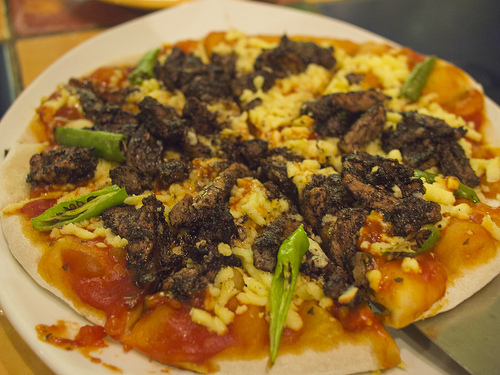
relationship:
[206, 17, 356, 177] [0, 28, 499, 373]
slice part of pizza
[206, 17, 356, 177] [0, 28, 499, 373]
slice cut from pizza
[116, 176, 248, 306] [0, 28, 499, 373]
topping on pizza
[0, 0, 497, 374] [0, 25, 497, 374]
white plate on table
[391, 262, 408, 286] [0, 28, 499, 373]
herb piece on pizza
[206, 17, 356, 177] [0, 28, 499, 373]
slice of pizza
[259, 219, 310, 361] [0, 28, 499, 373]
green pepper on pizza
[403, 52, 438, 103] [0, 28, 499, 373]
pepper on pizza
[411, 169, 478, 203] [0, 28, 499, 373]
pepper on pizza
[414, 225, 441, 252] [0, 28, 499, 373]
pepper on pizza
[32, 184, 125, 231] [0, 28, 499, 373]
pepper on pizza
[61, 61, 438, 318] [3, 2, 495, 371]
meat abundant on top of dish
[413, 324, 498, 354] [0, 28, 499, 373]
table beneath pizza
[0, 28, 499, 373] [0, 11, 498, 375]
pizza on table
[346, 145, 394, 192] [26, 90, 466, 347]
meat on taco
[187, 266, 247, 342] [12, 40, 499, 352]
yellow rice on burrito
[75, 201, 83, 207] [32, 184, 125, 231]
seeds in pepper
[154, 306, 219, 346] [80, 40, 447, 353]
salsa on burrito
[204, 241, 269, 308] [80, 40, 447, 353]
cheese on burrito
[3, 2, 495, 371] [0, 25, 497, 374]
dish on table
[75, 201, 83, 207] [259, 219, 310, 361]
seeds in green pepper